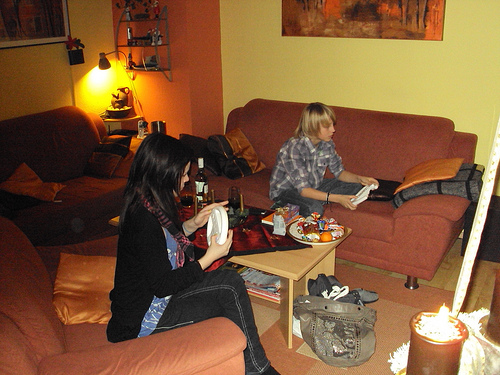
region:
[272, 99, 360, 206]
A boy of the sofa playing a game.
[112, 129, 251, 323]
A lady on the chair playing a game.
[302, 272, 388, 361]
Gray bag on the floor.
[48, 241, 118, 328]
An orange pillow next to woman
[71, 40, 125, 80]
A light shining on the wall.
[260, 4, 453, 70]
A picture on the wall.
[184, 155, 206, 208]
A bottle of liquor on the table.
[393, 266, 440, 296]
Leg of the sofa.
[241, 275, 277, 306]
Magazines under the table.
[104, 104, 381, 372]
Two people playing a racing game on the Wii.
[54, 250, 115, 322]
A gold square pillow.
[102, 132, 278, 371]
A girl holding a round wii steering wheel controller.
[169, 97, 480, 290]
A red sofa.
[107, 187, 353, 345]
A brown wooden coffee table.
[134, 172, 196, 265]
A pink and black scarf.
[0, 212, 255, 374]
A red armchair.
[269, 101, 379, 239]
A boy holding a round Wii steering wheel.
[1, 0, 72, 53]
A black framed picture on the wall.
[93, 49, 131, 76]
A small lamp.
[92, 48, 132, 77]
a bent desk lamp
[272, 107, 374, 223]
boy playing video game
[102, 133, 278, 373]
girl playing video game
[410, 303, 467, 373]
a candle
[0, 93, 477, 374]
a red sofa set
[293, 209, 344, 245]
a plate of food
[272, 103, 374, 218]
boy sitting on sofa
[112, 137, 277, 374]
girl sitting on sofa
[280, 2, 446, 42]
frameless picture hanging on wall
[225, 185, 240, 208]
a drinking glass with dark liquid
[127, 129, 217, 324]
this is a lady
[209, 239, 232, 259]
the lady is light skinned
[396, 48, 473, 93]
this is a wall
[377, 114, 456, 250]
this is a couch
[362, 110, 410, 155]
the couch is brown in color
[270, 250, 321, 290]
this is a table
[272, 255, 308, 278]
the table is wooden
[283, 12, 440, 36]
this is a picture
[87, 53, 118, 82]
this is a light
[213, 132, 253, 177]
this is a pillow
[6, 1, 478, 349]
Two childrens in the living room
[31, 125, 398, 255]
Childrens sitting in the brown color couch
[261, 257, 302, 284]
Wooden teapoy near the couch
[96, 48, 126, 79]
A light attached in the wall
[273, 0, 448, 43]
sceneries wallpaper attached in the wall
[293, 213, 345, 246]
Some eatable things kept in the teapoy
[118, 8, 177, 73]
Shelves attached in the wall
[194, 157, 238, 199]
A bottle and glass kept in the teapoy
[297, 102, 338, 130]
Brown color hair of the children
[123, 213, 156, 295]
A girl wearing black color sweater